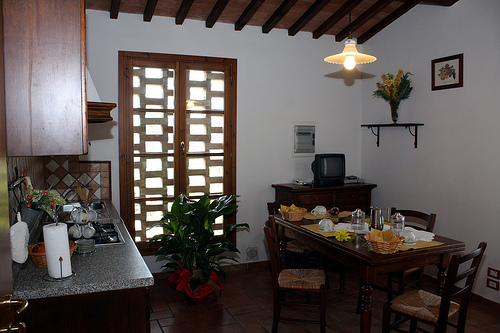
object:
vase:
[373, 69, 415, 123]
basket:
[278, 206, 308, 221]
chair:
[261, 215, 329, 333]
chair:
[380, 241, 488, 333]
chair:
[353, 207, 438, 315]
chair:
[267, 199, 291, 215]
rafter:
[312, 2, 360, 40]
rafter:
[286, 0, 329, 37]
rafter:
[204, 0, 228, 28]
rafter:
[233, 0, 263, 31]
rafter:
[142, 0, 158, 23]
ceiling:
[82, 0, 457, 45]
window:
[116, 50, 236, 257]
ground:
[240, 265, 272, 308]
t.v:
[310, 153, 346, 189]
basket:
[28, 241, 78, 269]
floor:
[166, 306, 212, 327]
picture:
[430, 53, 465, 92]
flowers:
[385, 80, 392, 88]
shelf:
[360, 122, 425, 149]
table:
[269, 210, 467, 332]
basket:
[363, 232, 405, 254]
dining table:
[267, 208, 468, 333]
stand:
[269, 177, 376, 217]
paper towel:
[42, 222, 73, 279]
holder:
[58, 256, 63, 280]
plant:
[145, 191, 252, 293]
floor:
[217, 279, 265, 332]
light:
[322, 39, 377, 71]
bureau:
[271, 180, 378, 221]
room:
[0, 0, 497, 333]